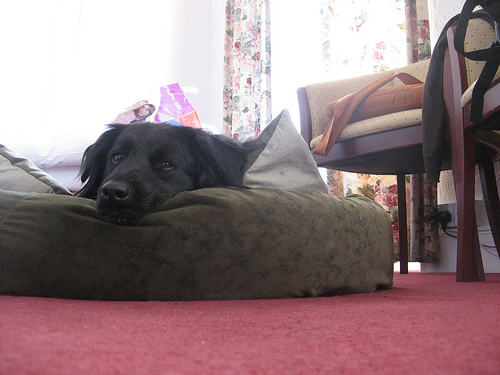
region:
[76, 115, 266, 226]
A DOG'S HEAD RESTING ON BED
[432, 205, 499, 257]
A BLACK POWER CORD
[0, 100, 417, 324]
A BROWN AND GRAY DOG BED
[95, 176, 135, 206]
A WET DOG NOSE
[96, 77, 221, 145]
A PLASTIC BAG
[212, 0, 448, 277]
WINDOW DRAPES WITH A FLORAL PATTERN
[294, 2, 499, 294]
A BROWN CHAIR MADE OF WOOD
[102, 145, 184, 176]
TWO SLEEPY DOG EYES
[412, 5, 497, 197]
THE ARM OF A SWEATSHIRT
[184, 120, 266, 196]
A HAIRY DOG EAR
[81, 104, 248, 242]
black dog laying down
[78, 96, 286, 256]
black dog looking at camera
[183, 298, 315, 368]
red floor next to dog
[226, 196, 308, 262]
soft surface dog is laying on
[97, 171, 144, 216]
black nose of the dog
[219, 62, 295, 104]
curtains near the dog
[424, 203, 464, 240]
outlet with a plug in it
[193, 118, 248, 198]
furry ears of the dog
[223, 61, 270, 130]
flower decoration on the curtains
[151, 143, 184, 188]
eye of the dog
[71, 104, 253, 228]
Dog sleeping on bed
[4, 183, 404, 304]
Bed of dog is green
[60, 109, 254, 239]
Dog is black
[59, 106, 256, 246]
Dog looks sad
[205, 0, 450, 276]
Flowery curtains cover the window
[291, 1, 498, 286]
Chairs on side of room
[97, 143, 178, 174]
Eyes of dog are black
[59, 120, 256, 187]
Ears of dog are long and pointy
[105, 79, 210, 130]
Picture on a girl on a cover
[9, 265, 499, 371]
CArpet on room is red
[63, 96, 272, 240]
a black dog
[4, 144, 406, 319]
a dog bed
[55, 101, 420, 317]
a dog on a dog bed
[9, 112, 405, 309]
a dog on a bed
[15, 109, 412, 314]
a dog bed with a dog on it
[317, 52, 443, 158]
a light brown bag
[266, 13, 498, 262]
a light brown bag on a chair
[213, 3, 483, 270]
flowered curtains on a window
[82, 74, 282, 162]
a shopping bag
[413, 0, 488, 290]
a black jacket on the back of a chair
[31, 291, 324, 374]
Red carpet on a floor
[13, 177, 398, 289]
Dog bed in a room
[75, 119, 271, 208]
Black dog on a bed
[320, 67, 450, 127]
Bag on a chair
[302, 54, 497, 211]
Chair in a room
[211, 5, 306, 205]
Curtains by a window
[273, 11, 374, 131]
Light coming from a window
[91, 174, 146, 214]
Nose on a dog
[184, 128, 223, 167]
Ear on a dog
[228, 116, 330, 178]
Pillow under a dog